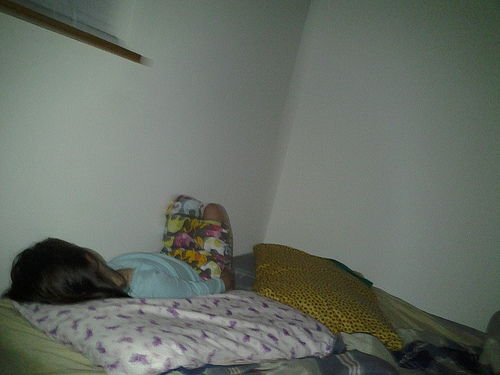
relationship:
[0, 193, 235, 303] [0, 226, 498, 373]
kid on bed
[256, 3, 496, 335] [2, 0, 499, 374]
wall in room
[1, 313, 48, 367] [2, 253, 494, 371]
sheets on bed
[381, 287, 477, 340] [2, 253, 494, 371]
sheets on bed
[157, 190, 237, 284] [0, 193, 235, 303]
flowery pants on kid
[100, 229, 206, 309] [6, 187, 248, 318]
t-shirt on girl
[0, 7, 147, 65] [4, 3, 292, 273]
shelf on wall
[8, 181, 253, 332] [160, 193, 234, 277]
kid wearing flowery pants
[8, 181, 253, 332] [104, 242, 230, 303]
kid wearing t-shirt